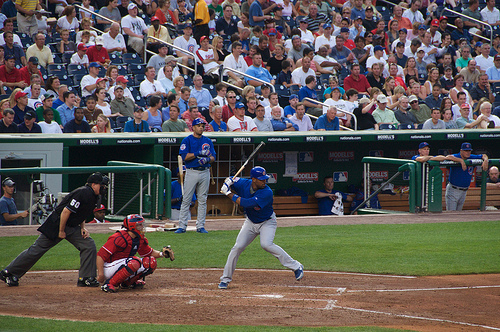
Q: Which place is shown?
A: It is a field.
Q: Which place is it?
A: It is a field.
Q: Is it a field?
A: Yes, it is a field.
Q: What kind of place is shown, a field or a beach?
A: It is a field.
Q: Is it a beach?
A: No, it is a field.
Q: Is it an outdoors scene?
A: Yes, it is outdoors.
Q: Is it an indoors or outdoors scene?
A: It is outdoors.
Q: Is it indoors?
A: No, it is outdoors.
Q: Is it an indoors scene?
A: No, it is outdoors.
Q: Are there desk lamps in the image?
A: No, there are no desk lamps.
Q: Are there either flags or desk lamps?
A: No, there are no desk lamps or flags.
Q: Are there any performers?
A: No, there are no performers.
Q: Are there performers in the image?
A: No, there are no performers.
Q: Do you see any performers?
A: No, there are no performers.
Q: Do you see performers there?
A: No, there are no performers.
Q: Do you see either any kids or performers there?
A: No, there are no performers or kids.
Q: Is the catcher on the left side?
A: Yes, the catcher is on the left of the image.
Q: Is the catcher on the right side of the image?
A: No, the catcher is on the left of the image.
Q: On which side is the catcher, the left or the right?
A: The catcher is on the left of the image.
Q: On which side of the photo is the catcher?
A: The catcher is on the left of the image.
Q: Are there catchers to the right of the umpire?
A: Yes, there is a catcher to the right of the umpire.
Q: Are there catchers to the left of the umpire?
A: No, the catcher is to the right of the umpire.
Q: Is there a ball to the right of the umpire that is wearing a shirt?
A: No, there is a catcher to the right of the umpire.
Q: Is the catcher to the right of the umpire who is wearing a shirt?
A: Yes, the catcher is to the right of the umpire.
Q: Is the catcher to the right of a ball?
A: No, the catcher is to the right of the umpire.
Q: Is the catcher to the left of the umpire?
A: No, the catcher is to the right of the umpire.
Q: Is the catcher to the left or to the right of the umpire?
A: The catcher is to the right of the umpire.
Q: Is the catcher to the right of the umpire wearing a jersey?
A: Yes, the catcher is wearing a jersey.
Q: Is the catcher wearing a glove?
A: No, the catcher is wearing a jersey.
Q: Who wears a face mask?
A: The catcher wears a face mask.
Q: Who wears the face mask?
A: The catcher wears a face mask.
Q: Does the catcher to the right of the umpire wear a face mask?
A: Yes, the catcher wears a face mask.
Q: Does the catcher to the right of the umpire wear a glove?
A: No, the catcher wears a face mask.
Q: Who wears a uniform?
A: The catcher wears a uniform.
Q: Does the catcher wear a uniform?
A: Yes, the catcher wears a uniform.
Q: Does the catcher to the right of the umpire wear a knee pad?
A: No, the catcher wears a uniform.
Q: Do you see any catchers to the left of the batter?
A: Yes, there is a catcher to the left of the batter.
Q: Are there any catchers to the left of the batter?
A: Yes, there is a catcher to the left of the batter.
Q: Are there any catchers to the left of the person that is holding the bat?
A: Yes, there is a catcher to the left of the batter.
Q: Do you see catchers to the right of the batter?
A: No, the catcher is to the left of the batter.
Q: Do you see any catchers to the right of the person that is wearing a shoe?
A: No, the catcher is to the left of the batter.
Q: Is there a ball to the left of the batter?
A: No, there is a catcher to the left of the batter.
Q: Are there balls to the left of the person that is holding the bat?
A: No, there is a catcher to the left of the batter.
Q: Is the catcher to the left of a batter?
A: Yes, the catcher is to the left of a batter.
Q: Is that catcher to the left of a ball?
A: No, the catcher is to the left of a batter.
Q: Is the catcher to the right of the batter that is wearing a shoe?
A: No, the catcher is to the left of the batter.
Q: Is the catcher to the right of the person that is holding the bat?
A: No, the catcher is to the left of the batter.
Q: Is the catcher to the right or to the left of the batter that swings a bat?
A: The catcher is to the left of the batter.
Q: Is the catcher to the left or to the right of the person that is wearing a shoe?
A: The catcher is to the left of the batter.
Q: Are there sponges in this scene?
A: No, there are no sponges.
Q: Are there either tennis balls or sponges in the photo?
A: No, there are no sponges or tennis balls.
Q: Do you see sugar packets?
A: No, there are no sugar packets.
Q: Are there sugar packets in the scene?
A: No, there are no sugar packets.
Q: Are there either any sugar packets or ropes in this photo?
A: No, there are no sugar packets or ropes.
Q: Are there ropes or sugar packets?
A: No, there are no sugar packets or ropes.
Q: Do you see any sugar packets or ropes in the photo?
A: No, there are no sugar packets or ropes.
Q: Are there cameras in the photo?
A: Yes, there is a camera.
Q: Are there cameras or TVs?
A: Yes, there is a camera.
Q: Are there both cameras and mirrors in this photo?
A: No, there is a camera but no mirrors.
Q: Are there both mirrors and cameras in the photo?
A: No, there is a camera but no mirrors.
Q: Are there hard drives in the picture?
A: No, there are no hard drives.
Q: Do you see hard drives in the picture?
A: No, there are no hard drives.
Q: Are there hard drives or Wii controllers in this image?
A: No, there are no hard drives or Wii controllers.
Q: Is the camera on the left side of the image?
A: Yes, the camera is on the left of the image.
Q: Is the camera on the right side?
A: No, the camera is on the left of the image.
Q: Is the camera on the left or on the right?
A: The camera is on the left of the image.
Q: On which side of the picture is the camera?
A: The camera is on the left of the image.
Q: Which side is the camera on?
A: The camera is on the left of the image.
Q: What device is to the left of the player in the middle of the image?
A: The device is a camera.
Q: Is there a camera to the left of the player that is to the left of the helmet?
A: Yes, there is a camera to the left of the player.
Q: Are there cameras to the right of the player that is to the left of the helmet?
A: No, the camera is to the left of the player.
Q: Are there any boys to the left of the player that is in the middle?
A: No, there is a camera to the left of the player.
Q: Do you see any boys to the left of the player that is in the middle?
A: No, there is a camera to the left of the player.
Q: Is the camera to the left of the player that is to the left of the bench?
A: Yes, the camera is to the left of the player.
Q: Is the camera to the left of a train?
A: No, the camera is to the left of the player.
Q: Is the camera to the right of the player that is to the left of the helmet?
A: No, the camera is to the left of the player.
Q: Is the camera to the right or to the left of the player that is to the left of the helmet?
A: The camera is to the left of the player.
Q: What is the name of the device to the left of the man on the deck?
A: The device is a camera.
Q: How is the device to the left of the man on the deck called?
A: The device is a camera.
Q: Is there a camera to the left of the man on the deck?
A: Yes, there is a camera to the left of the man.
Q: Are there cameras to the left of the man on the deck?
A: Yes, there is a camera to the left of the man.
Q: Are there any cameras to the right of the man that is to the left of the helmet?
A: No, the camera is to the left of the man.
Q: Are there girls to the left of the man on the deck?
A: No, there is a camera to the left of the man.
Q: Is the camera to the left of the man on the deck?
A: Yes, the camera is to the left of the man.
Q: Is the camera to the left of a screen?
A: No, the camera is to the left of the man.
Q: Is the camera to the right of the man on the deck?
A: No, the camera is to the left of the man.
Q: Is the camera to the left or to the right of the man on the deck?
A: The camera is to the left of the man.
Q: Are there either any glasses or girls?
A: No, there are no girls or glasses.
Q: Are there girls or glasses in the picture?
A: No, there are no girls or glasses.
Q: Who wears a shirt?
A: The man wears a shirt.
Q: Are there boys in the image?
A: No, there are no boys.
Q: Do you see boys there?
A: No, there are no boys.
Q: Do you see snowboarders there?
A: No, there are no snowboarders.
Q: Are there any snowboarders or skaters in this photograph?
A: No, there are no snowboarders or skaters.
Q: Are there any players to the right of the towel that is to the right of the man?
A: Yes, there is a player to the right of the towel.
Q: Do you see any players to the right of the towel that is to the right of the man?
A: Yes, there is a player to the right of the towel.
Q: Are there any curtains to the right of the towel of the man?
A: No, there is a player to the right of the towel.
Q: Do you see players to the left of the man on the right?
A: Yes, there is a player to the left of the man.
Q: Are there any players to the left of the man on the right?
A: Yes, there is a player to the left of the man.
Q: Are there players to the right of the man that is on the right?
A: No, the player is to the left of the man.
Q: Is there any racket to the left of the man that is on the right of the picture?
A: No, there is a player to the left of the man.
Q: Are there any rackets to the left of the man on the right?
A: No, there is a player to the left of the man.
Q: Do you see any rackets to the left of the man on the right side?
A: No, there is a player to the left of the man.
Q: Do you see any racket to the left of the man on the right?
A: No, there is a player to the left of the man.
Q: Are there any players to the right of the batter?
A: Yes, there is a player to the right of the batter.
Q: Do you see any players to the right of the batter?
A: Yes, there is a player to the right of the batter.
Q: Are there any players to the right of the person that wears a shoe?
A: Yes, there is a player to the right of the batter.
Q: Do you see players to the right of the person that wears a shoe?
A: Yes, there is a player to the right of the batter.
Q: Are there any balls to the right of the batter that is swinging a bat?
A: No, there is a player to the right of the batter.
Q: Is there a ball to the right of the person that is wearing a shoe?
A: No, there is a player to the right of the batter.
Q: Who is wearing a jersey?
A: The player is wearing a jersey.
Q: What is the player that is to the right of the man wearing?
A: The player is wearing a jersey.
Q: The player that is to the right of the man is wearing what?
A: The player is wearing a jersey.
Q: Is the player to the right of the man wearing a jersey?
A: Yes, the player is wearing a jersey.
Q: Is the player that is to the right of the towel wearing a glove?
A: No, the player is wearing a jersey.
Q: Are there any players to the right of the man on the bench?
A: Yes, there is a player to the right of the man.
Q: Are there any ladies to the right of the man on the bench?
A: No, there is a player to the right of the man.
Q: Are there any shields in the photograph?
A: No, there are no shields.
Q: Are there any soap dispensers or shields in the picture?
A: No, there are no shields or soap dispensers.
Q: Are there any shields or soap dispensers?
A: No, there are no shields or soap dispensers.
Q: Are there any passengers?
A: No, there are no passengers.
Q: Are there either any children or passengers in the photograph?
A: No, there are no passengers or children.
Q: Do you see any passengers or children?
A: No, there are no passengers or children.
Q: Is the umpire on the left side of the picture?
A: Yes, the umpire is on the left of the image.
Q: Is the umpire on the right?
A: No, the umpire is on the left of the image.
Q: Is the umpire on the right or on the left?
A: The umpire is on the left of the image.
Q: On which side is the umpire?
A: The umpire is on the left of the image.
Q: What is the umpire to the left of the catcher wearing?
A: The umpire is wearing a shirt.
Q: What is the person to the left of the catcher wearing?
A: The umpire is wearing a shirt.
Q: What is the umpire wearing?
A: The umpire is wearing a shirt.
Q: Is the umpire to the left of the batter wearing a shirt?
A: Yes, the umpire is wearing a shirt.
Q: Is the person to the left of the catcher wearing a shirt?
A: Yes, the umpire is wearing a shirt.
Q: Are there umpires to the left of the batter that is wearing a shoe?
A: Yes, there is an umpire to the left of the batter.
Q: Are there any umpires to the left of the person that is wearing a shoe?
A: Yes, there is an umpire to the left of the batter.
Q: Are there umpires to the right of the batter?
A: No, the umpire is to the left of the batter.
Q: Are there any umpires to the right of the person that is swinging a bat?
A: No, the umpire is to the left of the batter.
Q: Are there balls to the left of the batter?
A: No, there is an umpire to the left of the batter.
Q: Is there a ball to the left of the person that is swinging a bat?
A: No, there is an umpire to the left of the batter.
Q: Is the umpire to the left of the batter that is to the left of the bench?
A: Yes, the umpire is to the left of the batter.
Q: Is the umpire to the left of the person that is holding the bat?
A: Yes, the umpire is to the left of the batter.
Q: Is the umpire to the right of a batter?
A: No, the umpire is to the left of a batter.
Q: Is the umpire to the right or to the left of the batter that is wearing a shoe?
A: The umpire is to the left of the batter.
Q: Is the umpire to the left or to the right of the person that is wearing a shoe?
A: The umpire is to the left of the batter.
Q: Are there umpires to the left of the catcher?
A: Yes, there is an umpire to the left of the catcher.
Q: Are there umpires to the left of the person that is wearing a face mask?
A: Yes, there is an umpire to the left of the catcher.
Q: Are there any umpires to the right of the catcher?
A: No, the umpire is to the left of the catcher.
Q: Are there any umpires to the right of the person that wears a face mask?
A: No, the umpire is to the left of the catcher.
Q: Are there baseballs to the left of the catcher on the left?
A: No, there is an umpire to the left of the catcher.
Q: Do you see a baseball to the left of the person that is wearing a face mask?
A: No, there is an umpire to the left of the catcher.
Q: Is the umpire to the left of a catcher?
A: Yes, the umpire is to the left of a catcher.